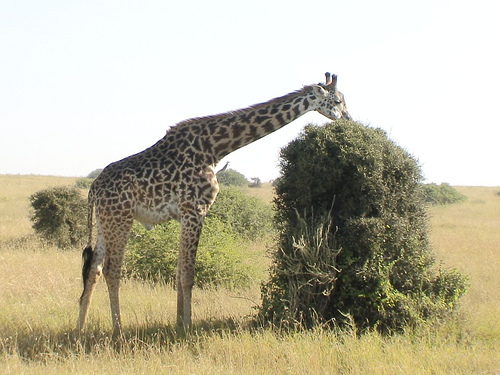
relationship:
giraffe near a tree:
[76, 72, 351, 344] [279, 109, 466, 334]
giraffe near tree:
[76, 72, 351, 344] [279, 109, 466, 334]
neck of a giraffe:
[211, 74, 316, 161] [76, 72, 351, 344]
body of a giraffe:
[97, 143, 214, 231] [76, 72, 351, 344]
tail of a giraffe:
[76, 189, 103, 302] [76, 72, 351, 344]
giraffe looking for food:
[76, 72, 351, 344] [327, 133, 375, 174]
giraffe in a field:
[76, 72, 351, 344] [247, 174, 498, 344]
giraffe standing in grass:
[76, 72, 351, 344] [241, 324, 419, 372]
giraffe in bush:
[76, 72, 351, 344] [279, 109, 466, 334]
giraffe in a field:
[76, 72, 351, 344] [3, 171, 496, 372]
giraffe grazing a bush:
[76, 72, 351, 344] [279, 109, 466, 334]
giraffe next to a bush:
[76, 72, 351, 344] [279, 109, 466, 334]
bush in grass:
[279, 109, 466, 334] [241, 324, 419, 372]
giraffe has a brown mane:
[76, 72, 351, 344] [187, 82, 314, 121]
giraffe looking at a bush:
[76, 72, 351, 344] [279, 109, 466, 334]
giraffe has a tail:
[76, 72, 351, 344] [78, 189, 99, 304]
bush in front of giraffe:
[279, 109, 466, 334] [76, 72, 351, 344]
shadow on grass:
[7, 312, 271, 346] [241, 324, 419, 372]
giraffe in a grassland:
[76, 72, 351, 344] [10, 236, 273, 368]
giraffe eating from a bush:
[76, 72, 351, 344] [279, 109, 466, 334]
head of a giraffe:
[295, 67, 358, 130] [76, 72, 351, 344]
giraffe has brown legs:
[76, 72, 351, 344] [160, 209, 217, 339]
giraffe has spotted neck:
[76, 72, 351, 344] [233, 112, 283, 141]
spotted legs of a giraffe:
[160, 209, 217, 339] [76, 72, 351, 344]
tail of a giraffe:
[78, 189, 99, 304] [76, 72, 351, 344]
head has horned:
[295, 67, 358, 130] [323, 70, 341, 90]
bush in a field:
[279, 109, 466, 334] [247, 174, 498, 344]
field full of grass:
[247, 174, 498, 344] [241, 324, 419, 372]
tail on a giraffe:
[76, 189, 103, 302] [76, 72, 351, 344]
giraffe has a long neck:
[76, 72, 351, 344] [211, 74, 316, 161]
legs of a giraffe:
[160, 209, 217, 339] [76, 72, 351, 344]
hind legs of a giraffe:
[78, 172, 147, 356] [76, 72, 351, 344]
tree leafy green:
[279, 109, 466, 334] [337, 141, 369, 247]